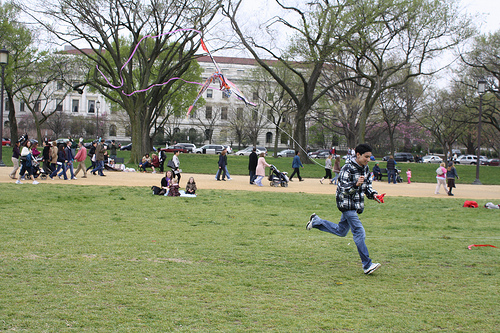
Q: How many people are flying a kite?
A: One.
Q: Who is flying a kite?
A: A guy.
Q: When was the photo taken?
A: Daytime.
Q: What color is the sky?
A: White.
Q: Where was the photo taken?
A: At a park.